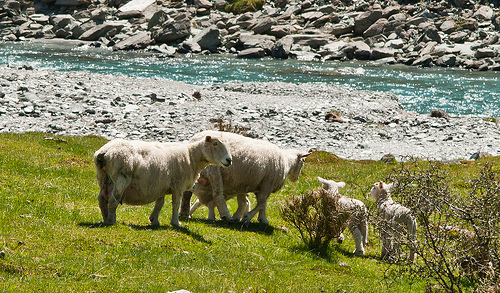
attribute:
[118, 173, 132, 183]
spots — black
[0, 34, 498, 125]
river — weak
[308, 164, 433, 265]
calf — small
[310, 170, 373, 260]
calf — white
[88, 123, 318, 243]
sheep — white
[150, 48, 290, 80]
water — blue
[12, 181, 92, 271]
grass — green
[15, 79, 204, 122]
rocks — gray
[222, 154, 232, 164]
nose — black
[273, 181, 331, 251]
bush — brown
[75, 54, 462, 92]
water — shallow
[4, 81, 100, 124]
rock — white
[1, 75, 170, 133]
river bed — white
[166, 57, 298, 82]
water — blue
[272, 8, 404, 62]
rocks — large, gray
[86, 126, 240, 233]
sheep — rear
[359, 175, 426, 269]
sheep — baby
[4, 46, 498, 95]
river — flowing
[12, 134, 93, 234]
grass — green, golden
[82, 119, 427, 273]
sheep — family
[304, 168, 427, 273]
lambs — small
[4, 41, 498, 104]
water — bright, blue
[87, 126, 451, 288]
sheep — family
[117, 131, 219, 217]
lamb — baby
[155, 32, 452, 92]
water — running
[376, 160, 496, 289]
trees — unbloomed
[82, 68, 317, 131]
beach — rocky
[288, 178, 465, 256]
sheep — baby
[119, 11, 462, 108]
bank — rocks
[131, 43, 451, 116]
water — blue, flowing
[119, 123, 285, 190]
sheep — looking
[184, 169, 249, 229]
lambs — hiding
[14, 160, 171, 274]
grass — green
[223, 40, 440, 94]
water — sparkling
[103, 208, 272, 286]
grass — short, green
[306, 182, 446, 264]
sheep — young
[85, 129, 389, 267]
sheep — guarding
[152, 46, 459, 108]
river — light blue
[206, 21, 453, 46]
rocks — large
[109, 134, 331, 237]
sheep — white, gray